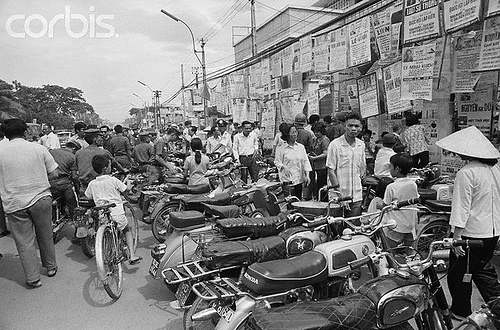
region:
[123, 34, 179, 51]
white clouds in the sky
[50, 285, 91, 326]
paved road for easier travel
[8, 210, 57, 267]
pants for covering legs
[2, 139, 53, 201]
shirts for covering torso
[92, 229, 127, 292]
wheels for moving bike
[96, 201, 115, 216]
seat for bike rider to sit on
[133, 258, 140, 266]
flip flops to protect feet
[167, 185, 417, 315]
row of bikes with motors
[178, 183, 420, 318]
motorcycles lined up side by side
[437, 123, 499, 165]
hat for protection from sun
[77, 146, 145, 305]
person riding a bike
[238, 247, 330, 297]
black seat of a motorcycle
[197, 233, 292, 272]
black seat of a motorcycle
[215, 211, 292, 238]
black seat of a motorcycle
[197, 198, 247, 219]
black seat of a motorcycle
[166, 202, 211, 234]
black seat of a motorcycle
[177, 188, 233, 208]
black seat of a motorcycle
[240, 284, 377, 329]
black seat of a motorcycle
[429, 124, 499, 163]
white cone shaped hat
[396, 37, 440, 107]
white flyer hanging in the wind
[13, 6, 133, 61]
company name on a photograph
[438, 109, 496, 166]
chinese hat on a man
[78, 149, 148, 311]
boy on a bicycle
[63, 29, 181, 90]
cloudy sky in the distance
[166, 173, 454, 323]
mopeds on the street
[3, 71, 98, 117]
leaves on a tree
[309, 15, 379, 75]
papers on the wall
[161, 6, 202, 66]
street lights on a pole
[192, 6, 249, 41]
electrical wires on a pole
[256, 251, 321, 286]
seat of a moped